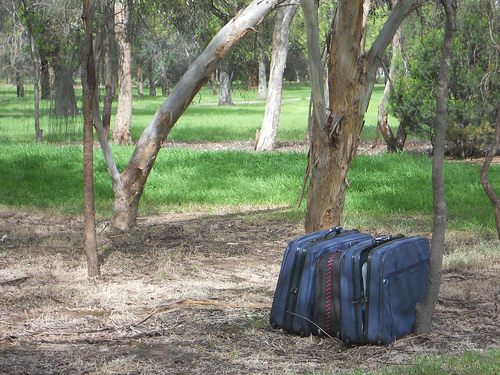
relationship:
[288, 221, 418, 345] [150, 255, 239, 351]
suitcase on ground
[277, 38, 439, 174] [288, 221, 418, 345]
tree near suitcase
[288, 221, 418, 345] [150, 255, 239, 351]
suitcase on top of ground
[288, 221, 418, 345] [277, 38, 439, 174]
suitcase near tree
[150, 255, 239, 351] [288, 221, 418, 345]
ground holding suitcase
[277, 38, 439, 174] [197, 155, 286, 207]
tree in grass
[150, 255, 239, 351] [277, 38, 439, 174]
ground holding tree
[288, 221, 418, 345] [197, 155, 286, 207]
suitcase near grass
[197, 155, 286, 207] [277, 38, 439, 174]
grass near tree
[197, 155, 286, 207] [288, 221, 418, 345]
grass near suitcase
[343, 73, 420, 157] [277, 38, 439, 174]
vines are hanging down tree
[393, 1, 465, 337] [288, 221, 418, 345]
tree at right of suitcase